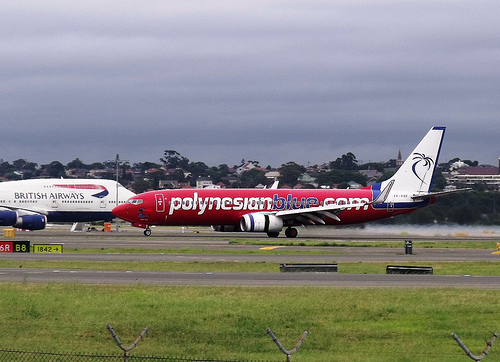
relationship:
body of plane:
[110, 187, 387, 225] [106, 116, 457, 242]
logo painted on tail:
[410, 147, 432, 187] [385, 120, 447, 200]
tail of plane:
[385, 120, 447, 200] [110, 123, 472, 222]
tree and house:
[42, 160, 64, 177] [235, 159, 259, 174]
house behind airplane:
[235, 159, 259, 174] [1, 170, 140, 227]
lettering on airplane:
[14, 189, 86, 199] [2, 176, 137, 228]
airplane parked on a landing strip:
[110, 126, 472, 239] [1, 204, 473, 254]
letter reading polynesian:
[168, 195, 181, 215] [167, 189, 272, 216]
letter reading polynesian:
[180, 197, 192, 209] [167, 189, 272, 216]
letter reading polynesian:
[195, 195, 208, 215] [167, 189, 272, 216]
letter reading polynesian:
[207, 195, 221, 210] [167, 189, 272, 216]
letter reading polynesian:
[221, 195, 233, 210] [167, 189, 272, 216]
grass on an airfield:
[4, 272, 498, 356] [1, 213, 498, 360]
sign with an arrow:
[33, 241, 63, 252] [52, 245, 62, 251]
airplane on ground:
[105, 119, 474, 259] [5, 220, 491, 357]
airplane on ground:
[2, 158, 143, 242] [5, 220, 491, 357]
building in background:
[451, 155, 499, 187] [2, 149, 498, 230]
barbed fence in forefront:
[0, 347, 250, 359] [8, 285, 498, 359]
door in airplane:
[155, 193, 165, 213] [108, 122, 473, 240]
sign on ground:
[33, 241, 63, 252] [5, 220, 491, 357]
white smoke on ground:
[281, 216, 499, 240] [12, 230, 484, 355]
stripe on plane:
[370, 182, 425, 214] [96, 122, 492, 245]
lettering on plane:
[169, 192, 370, 219] [106, 116, 457, 242]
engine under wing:
[240, 211, 283, 233] [260, 176, 394, 226]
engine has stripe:
[240, 211, 283, 233] [241, 206, 257, 233]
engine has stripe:
[240, 211, 283, 233] [259, 211, 274, 233]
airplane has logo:
[110, 126, 472, 239] [168, 191, 367, 214]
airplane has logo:
[0, 179, 138, 230] [13, 191, 83, 198]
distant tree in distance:
[318, 169, 368, 186] [2, 145, 497, 230]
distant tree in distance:
[446, 200, 474, 222] [2, 145, 497, 230]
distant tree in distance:
[237, 167, 267, 182] [2, 145, 497, 230]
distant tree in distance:
[277, 160, 306, 186] [2, 145, 497, 230]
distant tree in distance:
[158, 147, 188, 174] [2, 145, 497, 230]